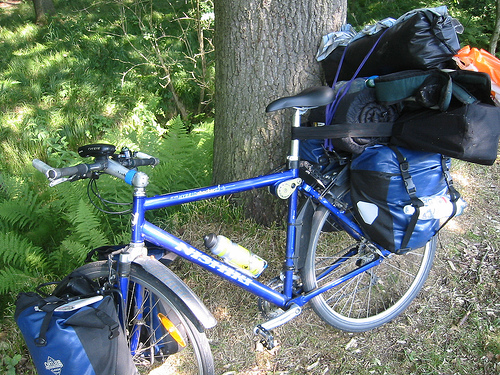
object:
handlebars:
[32, 153, 94, 189]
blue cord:
[322, 26, 389, 152]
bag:
[349, 144, 471, 257]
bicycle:
[19, 84, 442, 373]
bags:
[401, 78, 500, 168]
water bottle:
[198, 231, 269, 281]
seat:
[264, 83, 335, 118]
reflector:
[158, 311, 188, 348]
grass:
[1, 0, 217, 320]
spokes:
[313, 252, 368, 261]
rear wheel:
[296, 181, 441, 335]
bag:
[13, 286, 127, 372]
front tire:
[43, 259, 218, 374]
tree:
[209, 0, 353, 233]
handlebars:
[99, 144, 164, 169]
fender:
[93, 250, 217, 332]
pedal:
[253, 327, 287, 355]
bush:
[188, 22, 213, 127]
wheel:
[51, 257, 218, 372]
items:
[452, 44, 499, 102]